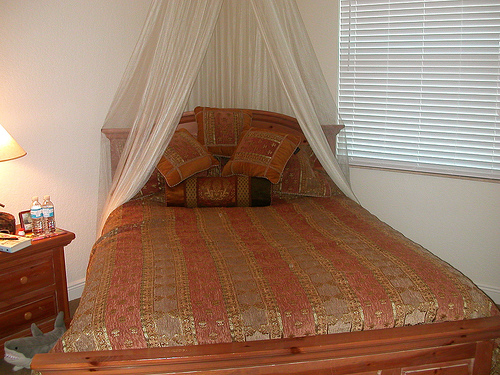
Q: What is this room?
A: Bedroom.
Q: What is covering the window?
A: Blinds.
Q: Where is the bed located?
A: Next to window.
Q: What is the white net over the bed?
A: Canopy.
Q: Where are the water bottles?
A: Night table.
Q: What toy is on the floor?
A: Stuffed shark.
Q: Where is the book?
A: Night stand.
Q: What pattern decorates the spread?
A: Striped brocade.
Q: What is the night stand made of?
A: Wood.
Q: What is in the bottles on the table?
A: Water.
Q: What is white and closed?
A: Blinds.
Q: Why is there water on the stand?
A: To drink.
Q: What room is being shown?
A: Bed.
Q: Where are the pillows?
A: Head of the bed.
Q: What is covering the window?
A: Blinds.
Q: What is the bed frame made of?
A: Wood.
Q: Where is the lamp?
A: On the table.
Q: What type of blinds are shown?
A: Horizontal.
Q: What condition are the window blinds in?
A: Closed.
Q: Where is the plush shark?
A: In the floor beside the bed.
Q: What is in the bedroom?
A: The wood bed.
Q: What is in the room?
A: A bed.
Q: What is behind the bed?
A: A canopy.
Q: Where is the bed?
A: In the bedroom.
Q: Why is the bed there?
A: For people to sleep on.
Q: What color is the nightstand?
A: Brown.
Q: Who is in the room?
A: Nobody.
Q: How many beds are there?
A: One.